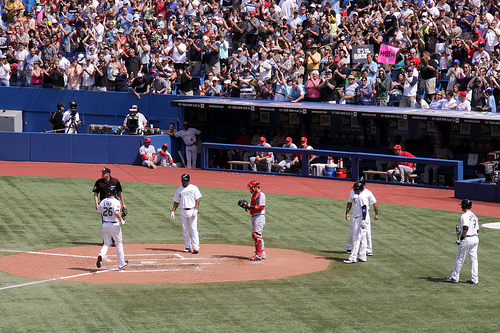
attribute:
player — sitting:
[248, 136, 276, 175]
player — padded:
[239, 181, 268, 262]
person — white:
[169, 173, 200, 256]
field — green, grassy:
[4, 163, 498, 332]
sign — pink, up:
[379, 44, 398, 65]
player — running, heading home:
[94, 184, 129, 278]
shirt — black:
[94, 179, 121, 195]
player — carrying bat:
[448, 200, 482, 291]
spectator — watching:
[3, 3, 499, 109]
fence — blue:
[0, 131, 174, 162]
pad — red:
[252, 232, 265, 258]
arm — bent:
[242, 201, 265, 214]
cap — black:
[102, 167, 112, 173]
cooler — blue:
[324, 165, 337, 175]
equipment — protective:
[249, 192, 262, 255]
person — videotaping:
[121, 105, 147, 131]